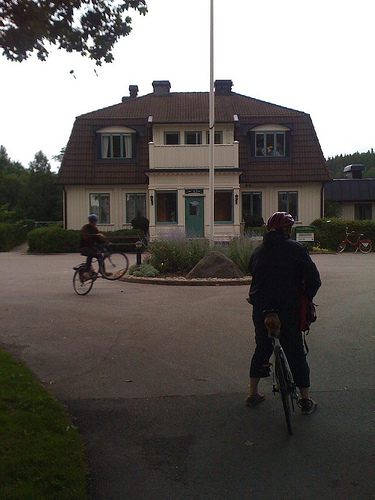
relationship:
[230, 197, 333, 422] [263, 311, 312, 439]
woman riding bike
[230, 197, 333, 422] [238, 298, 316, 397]
woman wearing pants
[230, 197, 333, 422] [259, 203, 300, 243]
woman wearing helmet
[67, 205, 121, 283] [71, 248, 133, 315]
boy on bike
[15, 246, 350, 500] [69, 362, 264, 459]
sidewalk has crack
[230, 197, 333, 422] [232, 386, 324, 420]
woman wearing shoes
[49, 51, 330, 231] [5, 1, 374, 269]
house in background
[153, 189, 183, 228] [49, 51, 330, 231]
window on house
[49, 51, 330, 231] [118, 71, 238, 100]
house has chimneys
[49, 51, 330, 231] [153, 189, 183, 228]
house has window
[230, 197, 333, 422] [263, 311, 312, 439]
woman on bike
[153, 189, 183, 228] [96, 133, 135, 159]
window with curtains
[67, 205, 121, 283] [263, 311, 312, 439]
boy on bike